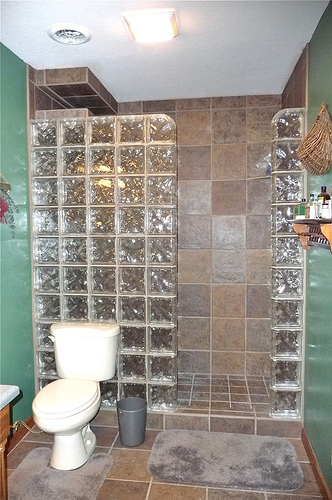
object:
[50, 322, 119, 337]
lid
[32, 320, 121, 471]
toilet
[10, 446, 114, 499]
rug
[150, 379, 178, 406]
tile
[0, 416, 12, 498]
cabinet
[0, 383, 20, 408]
counter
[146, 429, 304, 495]
rugs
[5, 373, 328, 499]
floor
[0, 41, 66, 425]
walls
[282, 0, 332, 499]
walls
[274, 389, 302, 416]
tile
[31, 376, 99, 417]
lid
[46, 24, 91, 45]
vent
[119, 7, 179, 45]
light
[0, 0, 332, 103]
ceiling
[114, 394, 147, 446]
trashcan